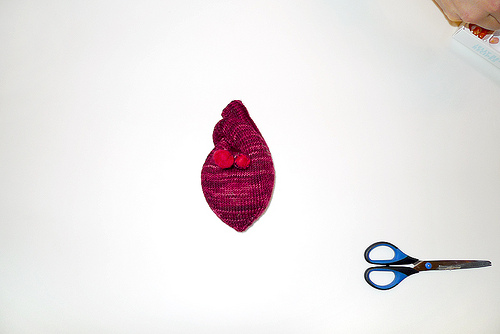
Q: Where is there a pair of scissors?
A: On the right.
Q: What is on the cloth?
A: Stripes.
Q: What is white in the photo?
A: The background.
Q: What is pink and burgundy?
A: The pouch.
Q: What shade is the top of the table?
A: White.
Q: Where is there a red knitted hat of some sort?
A: In the center.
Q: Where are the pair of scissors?
A: On a table.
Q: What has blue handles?
A: A pair of scissors.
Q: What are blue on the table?
A: The scissors.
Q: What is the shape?
A: Heart.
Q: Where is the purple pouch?
A: On the white surface.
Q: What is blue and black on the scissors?
A: The handle.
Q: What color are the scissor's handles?
A: Blue.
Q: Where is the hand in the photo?
A: Top right corner.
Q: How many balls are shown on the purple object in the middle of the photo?
A: Two.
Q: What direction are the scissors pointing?
A: Right.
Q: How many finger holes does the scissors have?
A: Two.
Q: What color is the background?
A: White.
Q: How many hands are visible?
A: One.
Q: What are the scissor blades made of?
A: Metal.